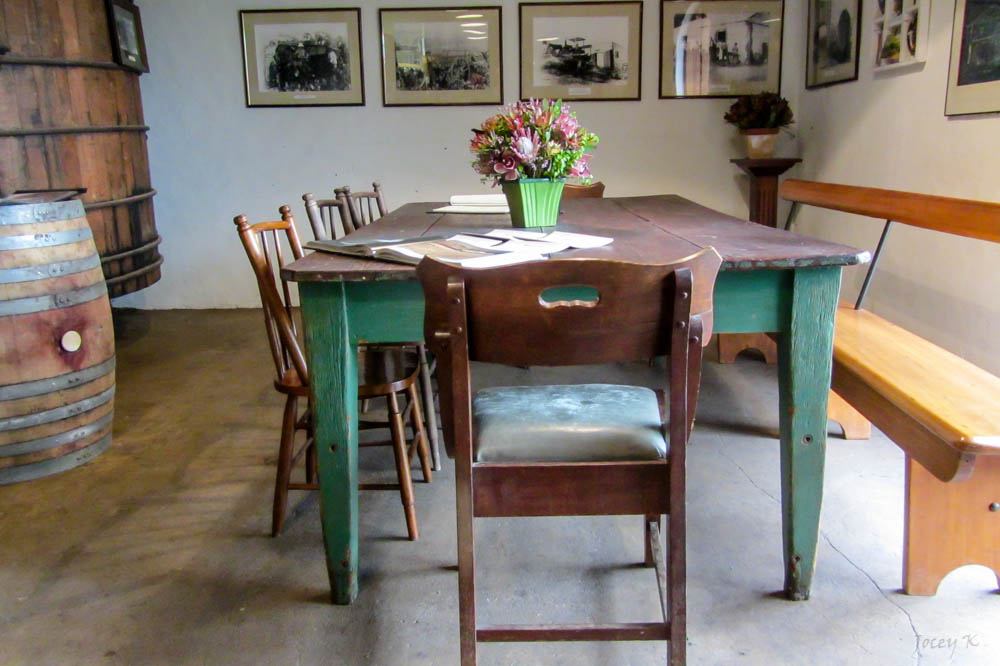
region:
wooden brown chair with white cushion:
[415, 250, 729, 664]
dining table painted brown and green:
[282, 191, 876, 609]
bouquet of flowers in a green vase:
[464, 96, 604, 233]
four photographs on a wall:
[234, 4, 789, 105]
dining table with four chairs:
[231, 181, 872, 663]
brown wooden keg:
[4, 191, 124, 485]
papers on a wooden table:
[288, 197, 878, 598]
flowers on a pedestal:
[718, 87, 805, 228]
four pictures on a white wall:
[150, 9, 798, 307]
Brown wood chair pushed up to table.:
[413, 260, 724, 641]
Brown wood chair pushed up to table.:
[233, 186, 407, 546]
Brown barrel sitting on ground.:
[2, 194, 113, 435]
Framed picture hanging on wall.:
[227, 7, 371, 125]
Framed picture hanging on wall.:
[375, 17, 519, 122]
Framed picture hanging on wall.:
[512, 4, 649, 108]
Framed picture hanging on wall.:
[652, 10, 784, 97]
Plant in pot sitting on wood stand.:
[730, 91, 797, 223]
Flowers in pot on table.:
[479, 96, 581, 207]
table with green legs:
[290, 161, 854, 596]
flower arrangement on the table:
[476, 91, 597, 235]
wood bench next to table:
[707, 175, 997, 593]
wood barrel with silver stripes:
[4, 191, 114, 469]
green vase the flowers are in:
[504, 171, 561, 225]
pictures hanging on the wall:
[234, 7, 996, 117]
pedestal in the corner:
[734, 154, 794, 222]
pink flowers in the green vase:
[461, 97, 596, 185]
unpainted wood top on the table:
[287, 160, 841, 285]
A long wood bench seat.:
[718, 172, 998, 599]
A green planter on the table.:
[495, 175, 565, 229]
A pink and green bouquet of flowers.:
[470, 95, 602, 192]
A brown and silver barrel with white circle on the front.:
[1, 187, 118, 489]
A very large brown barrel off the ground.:
[1, 4, 165, 299]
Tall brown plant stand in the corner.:
[730, 157, 802, 227]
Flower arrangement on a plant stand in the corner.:
[720, 92, 794, 159]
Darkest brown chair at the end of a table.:
[408, 254, 720, 664]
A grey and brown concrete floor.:
[7, 307, 998, 665]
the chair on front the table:
[400, 233, 732, 664]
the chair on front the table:
[289, 183, 366, 233]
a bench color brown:
[836, 289, 996, 606]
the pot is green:
[456, 85, 614, 237]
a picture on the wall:
[222, 2, 379, 122]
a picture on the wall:
[367, 6, 515, 117]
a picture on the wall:
[507, 3, 652, 114]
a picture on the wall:
[936, 0, 998, 125]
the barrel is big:
[0, 173, 131, 490]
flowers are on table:
[459, 90, 606, 231]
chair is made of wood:
[412, 275, 684, 653]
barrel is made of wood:
[8, 183, 150, 487]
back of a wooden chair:
[406, 235, 720, 627]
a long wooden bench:
[831, 301, 998, 623]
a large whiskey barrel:
[6, 193, 131, 485]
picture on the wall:
[229, 1, 367, 112]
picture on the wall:
[375, 7, 506, 102]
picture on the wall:
[516, 8, 640, 106]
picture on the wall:
[658, 1, 783, 96]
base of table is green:
[299, 273, 840, 608]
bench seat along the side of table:
[720, 169, 996, 591]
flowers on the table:
[470, 93, 600, 226]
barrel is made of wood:
[2, 185, 131, 491]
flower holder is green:
[500, 171, 572, 224]